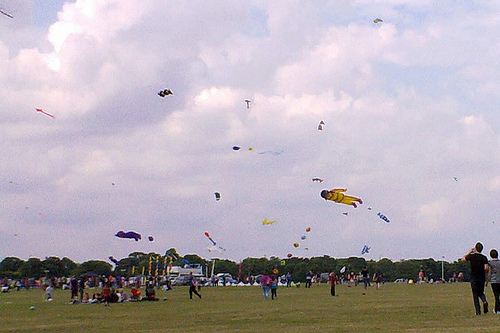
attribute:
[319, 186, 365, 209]
kite — yellow and black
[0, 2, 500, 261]
clouds — dark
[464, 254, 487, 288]
shirt — black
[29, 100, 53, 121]
kite — red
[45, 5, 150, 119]
clouds — fluffy, white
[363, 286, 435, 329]
grass — green, brown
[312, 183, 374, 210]
kite — yellow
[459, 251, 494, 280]
shirt — black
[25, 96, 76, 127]
kite — red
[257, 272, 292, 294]
shirt — purple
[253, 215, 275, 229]
kite — yellow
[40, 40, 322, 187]
clouds — big, white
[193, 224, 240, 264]
kite — blue, red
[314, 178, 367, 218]
kite — large, yellow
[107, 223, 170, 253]
kite — purple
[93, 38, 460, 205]
clouds — puffy, white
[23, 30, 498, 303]
sky — blue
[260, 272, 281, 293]
shirt — purple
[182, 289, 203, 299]
pants — black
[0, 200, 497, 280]
tree — green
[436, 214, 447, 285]
pole — white